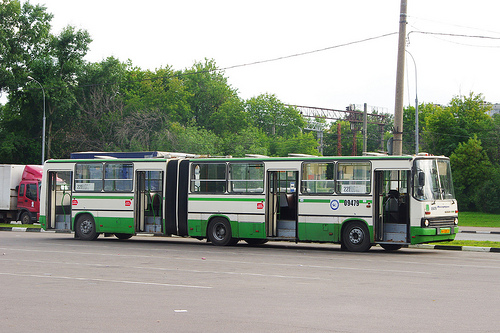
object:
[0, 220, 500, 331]
street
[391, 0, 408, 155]
utility pole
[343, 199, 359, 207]
number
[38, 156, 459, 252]
bus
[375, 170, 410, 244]
door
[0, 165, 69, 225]
truck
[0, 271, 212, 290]
line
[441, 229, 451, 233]
license plate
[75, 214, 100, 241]
tire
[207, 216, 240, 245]
tire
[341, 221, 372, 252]
tire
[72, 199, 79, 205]
sticker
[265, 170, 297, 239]
door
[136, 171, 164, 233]
door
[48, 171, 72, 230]
door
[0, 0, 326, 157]
trees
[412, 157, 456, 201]
windshield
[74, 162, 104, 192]
window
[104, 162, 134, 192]
window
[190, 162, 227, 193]
window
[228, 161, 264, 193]
window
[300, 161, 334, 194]
window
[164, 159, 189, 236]
connector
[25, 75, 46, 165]
light pole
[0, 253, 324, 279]
line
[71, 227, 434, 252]
bottom section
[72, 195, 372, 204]
stripe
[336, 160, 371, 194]
window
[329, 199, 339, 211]
circle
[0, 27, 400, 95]
electric lines